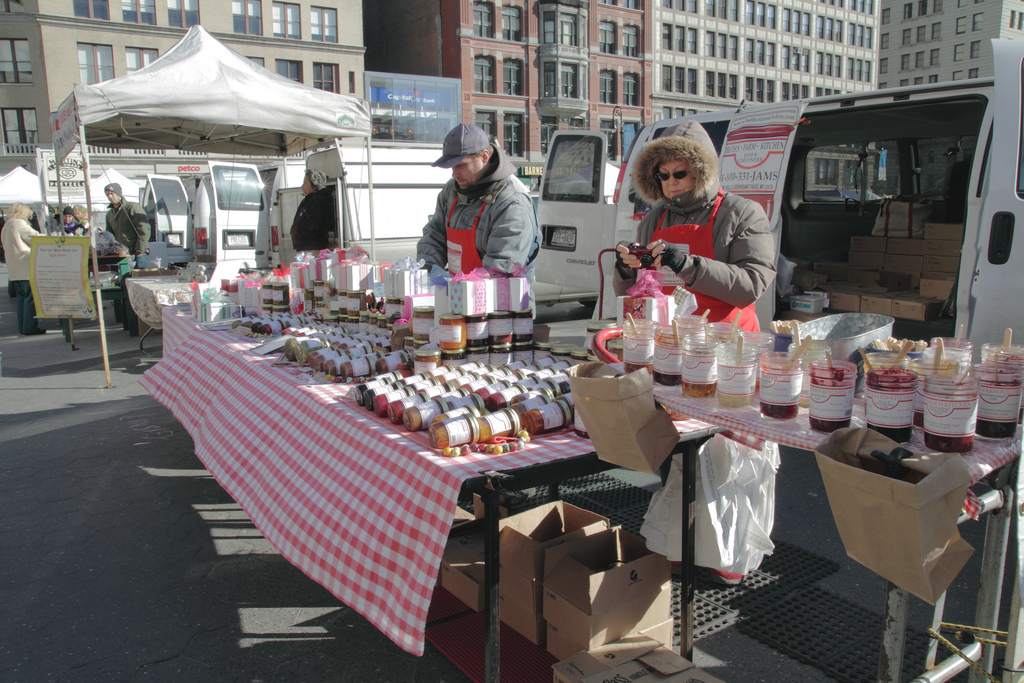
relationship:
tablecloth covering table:
[134, 299, 720, 656] [158, 297, 725, 676]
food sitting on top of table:
[186, 242, 584, 457] [158, 297, 725, 676]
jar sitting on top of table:
[428, 415, 481, 446] [158, 297, 725, 676]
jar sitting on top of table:
[471, 400, 524, 444] [158, 297, 725, 676]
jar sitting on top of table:
[521, 394, 578, 433] [158, 297, 725, 676]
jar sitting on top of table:
[400, 394, 450, 431] [158, 297, 725, 676]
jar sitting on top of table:
[478, 376, 531, 416] [158, 297, 725, 676]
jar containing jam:
[428, 415, 481, 446] [423, 417, 476, 452]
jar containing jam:
[471, 400, 524, 444] [469, 405, 517, 447]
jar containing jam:
[521, 394, 578, 433] [519, 396, 571, 435]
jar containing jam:
[400, 394, 450, 431] [397, 394, 445, 429]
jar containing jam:
[478, 376, 531, 416] [482, 392, 515, 410]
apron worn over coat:
[648, 186, 761, 344] [609, 113, 778, 332]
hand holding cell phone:
[611, 238, 644, 271] [629, 243, 664, 272]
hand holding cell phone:
[646, 236, 690, 275] [629, 243, 664, 272]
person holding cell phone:
[613, 119, 777, 585] [629, 243, 664, 272]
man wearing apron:
[417, 111, 545, 315] [435, 199, 490, 267]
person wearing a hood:
[613, 119, 777, 585] [621, 117, 723, 213]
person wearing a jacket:
[613, 119, 777, 585] [612, 113, 783, 295]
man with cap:
[417, 123, 544, 321] [427, 116, 510, 171]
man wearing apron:
[417, 123, 544, 321] [438, 182, 488, 275]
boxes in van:
[796, 214, 963, 340] [535, 37, 991, 364]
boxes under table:
[459, 493, 676, 679] [158, 297, 725, 676]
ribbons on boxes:
[448, 266, 522, 284] [444, 260, 533, 328]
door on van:
[710, 89, 804, 323] [533, 70, 991, 366]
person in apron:
[602, 107, 773, 358] [637, 182, 759, 338]